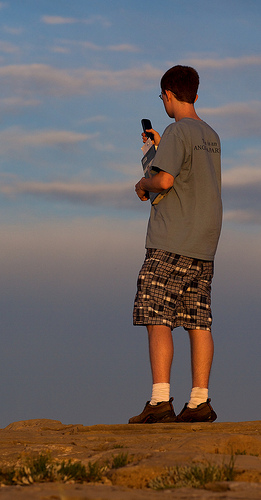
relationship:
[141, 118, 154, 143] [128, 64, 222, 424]
phone held by boy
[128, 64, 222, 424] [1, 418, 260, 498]
boy on ground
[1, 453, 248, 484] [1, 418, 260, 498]
grass on ground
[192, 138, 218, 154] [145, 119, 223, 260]
writing on shirt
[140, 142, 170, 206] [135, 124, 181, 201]
book under arm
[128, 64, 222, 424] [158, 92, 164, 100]
boy wearing glasses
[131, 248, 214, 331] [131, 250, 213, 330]
shorts have squares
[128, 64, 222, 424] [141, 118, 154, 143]
boy holding phone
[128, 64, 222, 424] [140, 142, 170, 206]
boy holding book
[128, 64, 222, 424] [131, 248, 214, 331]
boy wears shorts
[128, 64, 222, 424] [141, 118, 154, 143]
boy using phone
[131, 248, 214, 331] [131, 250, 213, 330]
shorts with squares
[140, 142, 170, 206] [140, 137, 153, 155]
book with paper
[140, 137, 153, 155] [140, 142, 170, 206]
paper in book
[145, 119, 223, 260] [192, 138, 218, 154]
shirt with writing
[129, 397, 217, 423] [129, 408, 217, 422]
shoes with soles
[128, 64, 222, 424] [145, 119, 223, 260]
boy wearing shirt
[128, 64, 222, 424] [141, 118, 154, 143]
boy looking at phone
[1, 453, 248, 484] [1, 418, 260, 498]
grass in ground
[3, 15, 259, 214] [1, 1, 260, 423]
clouds in sky